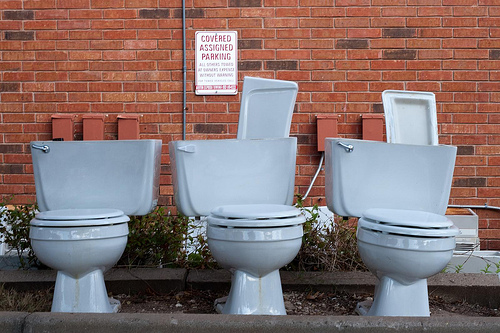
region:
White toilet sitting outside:
[26, 139, 163, 314]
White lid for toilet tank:
[239, 73, 297, 142]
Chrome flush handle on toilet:
[29, 142, 48, 156]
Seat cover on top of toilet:
[365, 210, 451, 230]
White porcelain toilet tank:
[320, 138, 455, 213]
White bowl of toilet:
[355, 244, 452, 277]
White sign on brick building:
[190, 33, 237, 100]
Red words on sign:
[197, 33, 229, 84]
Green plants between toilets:
[143, 213, 205, 268]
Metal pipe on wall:
[450, 201, 498, 211]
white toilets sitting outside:
[0, 82, 470, 319]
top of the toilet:
[351, 181, 462, 256]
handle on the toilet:
[329, 124, 366, 164]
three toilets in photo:
[16, 104, 470, 297]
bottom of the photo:
[222, 268, 292, 323]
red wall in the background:
[40, 22, 148, 86]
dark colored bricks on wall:
[308, 15, 433, 84]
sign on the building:
[173, 13, 253, 106]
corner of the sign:
[218, 18, 248, 43]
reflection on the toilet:
[223, 212, 301, 259]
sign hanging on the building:
[179, 28, 259, 112]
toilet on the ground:
[154, 78, 318, 298]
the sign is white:
[182, 19, 236, 104]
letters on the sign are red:
[186, 16, 236, 131]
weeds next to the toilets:
[128, 212, 218, 281]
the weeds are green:
[117, 200, 215, 313]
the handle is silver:
[23, 128, 81, 185]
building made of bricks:
[59, 18, 173, 98]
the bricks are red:
[46, 32, 150, 135]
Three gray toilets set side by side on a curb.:
[3, 137, 498, 332]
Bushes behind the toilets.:
[0, 204, 377, 274]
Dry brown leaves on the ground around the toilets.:
[0, 283, 499, 317]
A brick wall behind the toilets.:
[0, 27, 497, 252]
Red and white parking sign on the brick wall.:
[196, 31, 239, 96]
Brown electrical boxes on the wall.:
[48, 109, 382, 156]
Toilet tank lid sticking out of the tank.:
[170, 76, 295, 215]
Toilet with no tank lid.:
[29, 137, 160, 312]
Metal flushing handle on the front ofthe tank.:
[176, 144, 197, 156]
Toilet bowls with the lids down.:
[26, 137, 461, 316]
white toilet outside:
[18, 122, 160, 332]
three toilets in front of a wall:
[13, 97, 478, 313]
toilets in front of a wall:
[161, 76, 475, 331]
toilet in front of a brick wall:
[19, 38, 168, 314]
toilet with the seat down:
[355, 196, 462, 303]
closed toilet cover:
[203, 199, 307, 299]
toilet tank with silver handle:
[27, 143, 159, 212]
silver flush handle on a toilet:
[332, 137, 362, 162]